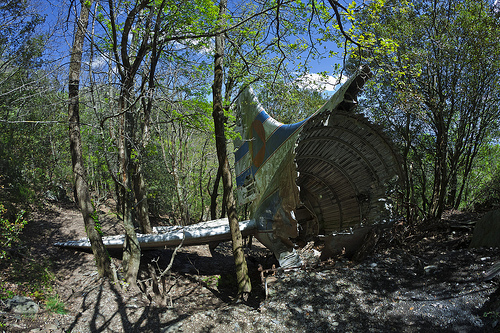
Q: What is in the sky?
A: Clouds.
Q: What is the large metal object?
A: Part of an airplane.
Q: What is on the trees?
A: Green leaves.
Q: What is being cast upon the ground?
A: Shadows.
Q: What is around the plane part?
A: Trees.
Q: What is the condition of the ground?
A: Bare.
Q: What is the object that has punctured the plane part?
A: Log.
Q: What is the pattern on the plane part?
A: Stripes.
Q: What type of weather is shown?
A: Clear.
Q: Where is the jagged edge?
A: Edge of the plane.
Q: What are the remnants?
A: Of the plane.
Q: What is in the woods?
A: Half of the plane.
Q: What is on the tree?
A: Green leaves.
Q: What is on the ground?
A: Shadow of the tree.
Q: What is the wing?
A: Of the plane.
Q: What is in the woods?
A: The plane.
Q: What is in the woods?
A: The airplane.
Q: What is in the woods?
A: The tail of the airplane.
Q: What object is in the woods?
A: Tail of a plane.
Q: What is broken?
A: An airplane.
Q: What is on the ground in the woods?
A: A broken plane.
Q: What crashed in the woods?
A: A plane.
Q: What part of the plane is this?
A: The tail.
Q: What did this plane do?
A: It crashed.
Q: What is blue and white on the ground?
A: The plane tail.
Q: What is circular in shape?
A: The plane tail.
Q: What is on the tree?
A: Thin branches.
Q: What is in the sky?
A: Clouds.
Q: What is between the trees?
A: A tail.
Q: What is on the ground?
A: Wing of plane.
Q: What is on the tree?
A: Branches.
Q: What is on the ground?
A: Dirt.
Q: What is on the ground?
A: Part of the plane.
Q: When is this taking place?
A: Daytime.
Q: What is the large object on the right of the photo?
A: Tunnel.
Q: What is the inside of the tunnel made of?
A: Wood.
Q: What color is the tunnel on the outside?
A: Blue, gold and white.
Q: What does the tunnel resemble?
A: Airplane.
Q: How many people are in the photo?
A: None.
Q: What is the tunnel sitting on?
A: Dirt ground.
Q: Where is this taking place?
A: In the forest.